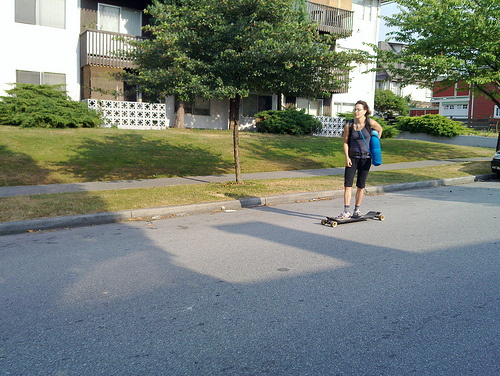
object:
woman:
[339, 100, 383, 223]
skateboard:
[320, 210, 385, 228]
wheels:
[321, 215, 385, 227]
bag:
[370, 129, 382, 166]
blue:
[373, 141, 380, 151]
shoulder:
[365, 117, 377, 130]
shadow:
[46, 132, 235, 182]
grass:
[0, 125, 498, 211]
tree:
[109, 0, 368, 187]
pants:
[344, 157, 372, 188]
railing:
[81, 28, 155, 70]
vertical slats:
[94, 33, 107, 67]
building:
[404, 75, 499, 130]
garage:
[438, 96, 475, 120]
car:
[490, 135, 500, 178]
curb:
[0, 173, 499, 236]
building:
[0, 0, 386, 140]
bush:
[1, 83, 107, 128]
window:
[15, 70, 66, 101]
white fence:
[80, 98, 173, 130]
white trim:
[469, 84, 475, 121]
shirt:
[348, 117, 371, 159]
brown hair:
[355, 99, 372, 116]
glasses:
[354, 107, 367, 111]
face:
[354, 104, 365, 119]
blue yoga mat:
[370, 129, 383, 166]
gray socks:
[344, 204, 361, 212]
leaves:
[167, 11, 208, 33]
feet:
[335, 208, 361, 220]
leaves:
[26, 228, 79, 233]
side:
[0, 196, 267, 237]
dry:
[26, 229, 34, 233]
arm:
[369, 118, 383, 139]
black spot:
[277, 267, 291, 271]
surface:
[0, 187, 500, 376]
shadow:
[216, 187, 332, 223]